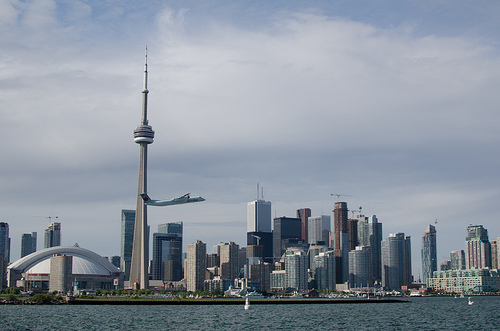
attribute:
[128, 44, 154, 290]
space needle — tall, skinny, futuristic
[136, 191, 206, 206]
plane — flying, departing, white, low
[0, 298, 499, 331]
lake — large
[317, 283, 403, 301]
boats — docked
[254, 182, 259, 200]
spire — transmitting, modern, communicating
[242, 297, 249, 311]
buoy — designating, white, bobbing, floating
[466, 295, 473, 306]
buoy — designating, white, bobbing, floating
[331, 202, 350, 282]
building — unfinished, tall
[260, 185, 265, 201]
spire — communicating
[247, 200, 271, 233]
building — white, tall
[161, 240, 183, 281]
building — modern, glass, reflecting, tall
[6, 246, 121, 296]
building — round, low, domed, distant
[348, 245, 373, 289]
building — brown, circular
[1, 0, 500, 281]
sky — cloudy, white, blue, behind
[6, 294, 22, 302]
bush — green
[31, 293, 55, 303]
bush — green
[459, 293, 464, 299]
boat — small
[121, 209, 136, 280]
building — tall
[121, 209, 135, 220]
top — sloping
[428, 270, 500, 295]
building — low, large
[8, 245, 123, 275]
roof — domed